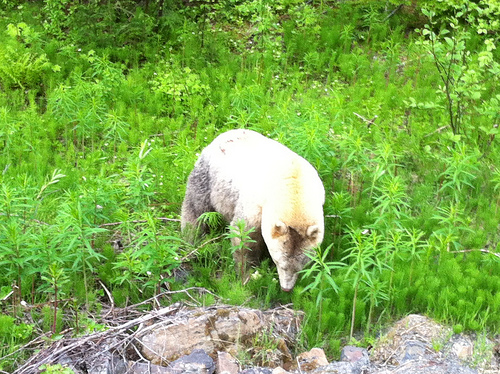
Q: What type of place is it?
A: It is a forest.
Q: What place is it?
A: It is a forest.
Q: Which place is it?
A: It is a forest.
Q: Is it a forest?
A: Yes, it is a forest.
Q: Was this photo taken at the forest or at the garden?
A: It was taken at the forest.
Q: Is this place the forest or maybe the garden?
A: It is the forest.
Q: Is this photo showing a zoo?
A: No, the picture is showing a forest.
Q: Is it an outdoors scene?
A: Yes, it is outdoors.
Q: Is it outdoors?
A: Yes, it is outdoors.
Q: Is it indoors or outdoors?
A: It is outdoors.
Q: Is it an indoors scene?
A: No, it is outdoors.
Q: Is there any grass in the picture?
A: Yes, there is grass.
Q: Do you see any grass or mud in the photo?
A: Yes, there is grass.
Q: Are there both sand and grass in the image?
A: No, there is grass but no sand.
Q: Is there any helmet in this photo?
A: No, there are no helmets.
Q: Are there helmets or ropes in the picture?
A: No, there are no helmets or ropes.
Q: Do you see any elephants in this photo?
A: No, there are no elephants.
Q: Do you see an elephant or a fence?
A: No, there are no elephants or fences.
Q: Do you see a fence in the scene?
A: No, there are no fences.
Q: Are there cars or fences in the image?
A: No, there are no fences or cars.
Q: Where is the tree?
A: The tree is in the forest.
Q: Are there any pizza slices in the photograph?
A: No, there are no pizza slices.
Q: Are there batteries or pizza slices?
A: No, there are no pizza slices or batteries.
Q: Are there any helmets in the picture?
A: No, there are no helmets.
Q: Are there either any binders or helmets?
A: No, there are no helmets or binders.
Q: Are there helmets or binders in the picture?
A: No, there are no helmets or binders.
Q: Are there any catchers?
A: No, there are no catchers.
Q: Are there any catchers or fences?
A: No, there are no catchers or fences.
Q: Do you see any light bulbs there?
A: No, there are no light bulbs.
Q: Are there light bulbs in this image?
A: No, there are no light bulbs.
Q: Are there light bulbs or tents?
A: No, there are no light bulbs or tents.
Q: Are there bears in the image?
A: Yes, there is a bear.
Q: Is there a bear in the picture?
A: Yes, there is a bear.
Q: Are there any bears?
A: Yes, there is a bear.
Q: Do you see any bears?
A: Yes, there is a bear.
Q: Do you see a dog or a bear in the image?
A: Yes, there is a bear.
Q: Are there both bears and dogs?
A: No, there is a bear but no dogs.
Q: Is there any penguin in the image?
A: No, there are no penguins.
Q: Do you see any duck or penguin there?
A: No, there are no penguins or ducks.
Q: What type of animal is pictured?
A: The animal is a bear.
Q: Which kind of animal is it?
A: The animal is a bear.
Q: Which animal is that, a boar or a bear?
A: This is a bear.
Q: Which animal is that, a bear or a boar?
A: This is a bear.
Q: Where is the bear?
A: The bear is in the grass.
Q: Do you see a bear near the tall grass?
A: Yes, there is a bear near the grass.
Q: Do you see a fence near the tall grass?
A: No, there is a bear near the grass.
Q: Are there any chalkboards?
A: No, there are no chalkboards.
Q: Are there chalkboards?
A: No, there are no chalkboards.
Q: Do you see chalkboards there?
A: No, there are no chalkboards.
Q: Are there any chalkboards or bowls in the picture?
A: No, there are no chalkboards or bowls.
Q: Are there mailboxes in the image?
A: No, there are no mailboxes.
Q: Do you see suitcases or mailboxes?
A: No, there are no mailboxes or suitcases.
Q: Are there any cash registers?
A: No, there are no cash registers.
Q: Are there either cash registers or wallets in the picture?
A: No, there are no cash registers or wallets.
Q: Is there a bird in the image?
A: No, there are no birds.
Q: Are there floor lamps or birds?
A: No, there are no birds or floor lamps.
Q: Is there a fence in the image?
A: No, there are no fences.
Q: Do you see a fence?
A: No, there are no fences.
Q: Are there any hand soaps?
A: No, there are no hand soaps.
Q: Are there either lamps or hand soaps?
A: No, there are no hand soaps or lamps.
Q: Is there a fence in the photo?
A: No, there are no fences.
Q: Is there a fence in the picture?
A: No, there are no fences.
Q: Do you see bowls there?
A: No, there are no bowls.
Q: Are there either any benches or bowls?
A: No, there are no bowls or benches.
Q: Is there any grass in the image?
A: Yes, there is grass.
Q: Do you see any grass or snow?
A: Yes, there is grass.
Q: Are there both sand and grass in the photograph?
A: No, there is grass but no sand.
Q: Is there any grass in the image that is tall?
A: Yes, there is grass that is tall.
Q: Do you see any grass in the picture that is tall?
A: Yes, there is grass that is tall.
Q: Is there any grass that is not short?
A: Yes, there is tall grass.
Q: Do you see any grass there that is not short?
A: Yes, there is tall grass.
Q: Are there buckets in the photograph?
A: No, there are no buckets.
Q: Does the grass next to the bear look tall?
A: Yes, the grass is tall.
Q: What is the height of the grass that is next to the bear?
A: The grass is tall.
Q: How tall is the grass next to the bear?
A: The grass is tall.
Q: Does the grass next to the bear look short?
A: No, the grass is tall.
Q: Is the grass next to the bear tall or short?
A: The grass is tall.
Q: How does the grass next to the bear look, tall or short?
A: The grass is tall.